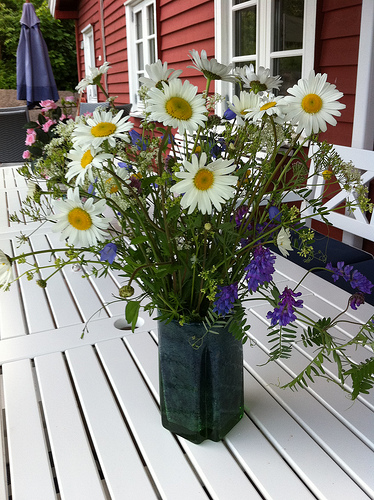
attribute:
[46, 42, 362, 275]
daisies — white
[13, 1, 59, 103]
umbrella — blue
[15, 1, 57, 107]
umbrella — purple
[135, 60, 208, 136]
flowers — white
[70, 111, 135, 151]
flower — white and yellow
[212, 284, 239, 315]
flower — purple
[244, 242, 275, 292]
flower — purple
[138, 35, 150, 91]
window — house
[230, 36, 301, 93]
window — house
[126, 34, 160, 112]
trim — white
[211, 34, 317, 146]
trim — white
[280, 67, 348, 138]
flower — white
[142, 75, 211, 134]
flower — white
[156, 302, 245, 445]
vase — flower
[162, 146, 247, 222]
daisy — yellow and white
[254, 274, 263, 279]
petals — purple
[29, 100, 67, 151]
flowers — pink, group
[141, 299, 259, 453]
vase — dark blue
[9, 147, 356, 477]
table — long, white